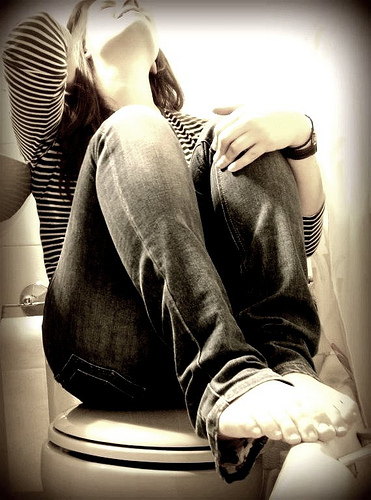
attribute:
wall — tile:
[0, 88, 47, 314]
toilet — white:
[39, 403, 370, 498]